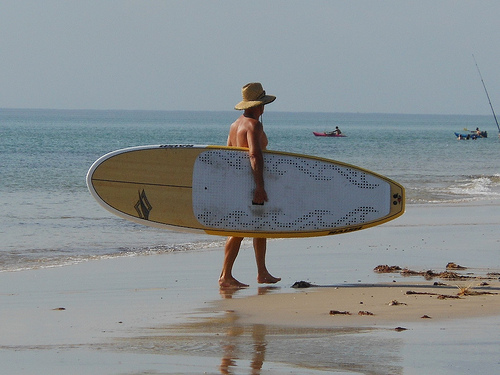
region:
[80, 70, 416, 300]
A surfer on the beach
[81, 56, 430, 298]
A male surfer on the beach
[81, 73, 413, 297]
A person walking on the beach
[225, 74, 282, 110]
A brown sunhat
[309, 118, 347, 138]
A person in the water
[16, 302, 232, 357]
The wet sand on the beach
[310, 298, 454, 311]
The dry sand on the beach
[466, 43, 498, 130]
A tall pole in the sky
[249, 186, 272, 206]
The right hand of the man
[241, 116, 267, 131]
The right shoulder of the man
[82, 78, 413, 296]
a man carrying a surf board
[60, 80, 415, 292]
a man walking on the beach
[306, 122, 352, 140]
a woman jet skiing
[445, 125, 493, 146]
people on a boat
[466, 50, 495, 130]
the end of a fishing rod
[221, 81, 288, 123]
a man wearing a straw hat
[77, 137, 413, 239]
a white, black, and wood designed surf board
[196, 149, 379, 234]
a black and white design on a surf board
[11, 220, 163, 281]
the ocean washing up on the beach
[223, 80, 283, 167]
a man not wearing a shirt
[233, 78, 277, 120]
the head of a man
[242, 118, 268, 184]
the arm of a man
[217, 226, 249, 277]
the leg of a man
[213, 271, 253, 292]
the foot of a man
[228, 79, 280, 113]
a brown straw hat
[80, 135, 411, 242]
a brown and white surfboard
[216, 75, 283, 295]
a man on the beach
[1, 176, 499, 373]
a brown sandy beach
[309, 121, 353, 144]
a red jet ski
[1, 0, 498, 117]
a clear sky overhead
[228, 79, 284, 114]
THE MAN IS WEARING A HAT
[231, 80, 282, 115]
THE MAN'S HAT IS A STRAW HAT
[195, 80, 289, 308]
THE MAN IS WALKING ON THE BEACH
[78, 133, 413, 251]
THE MAN IS CARRYING A SURF BOARD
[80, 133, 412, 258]
THE SURFBOARD IS HUGE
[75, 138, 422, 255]
THE SURFBOARD IS WOODEN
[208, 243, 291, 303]
THE MAN IS BAREFOOT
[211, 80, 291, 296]
THE MAN IS SHIRTLESS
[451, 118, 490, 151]
THE MAN IS IN THE WATER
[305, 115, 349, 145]
THE MAN IS ON A KAYAK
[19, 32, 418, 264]
this is on a beach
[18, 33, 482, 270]
this is along a coast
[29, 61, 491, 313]
this is an outdoor photo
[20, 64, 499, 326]
this is along an ocean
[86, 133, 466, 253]
this is a surfboard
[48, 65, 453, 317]
this man is a surfer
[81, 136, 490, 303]
the board is white and yellow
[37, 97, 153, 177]
this is an ocean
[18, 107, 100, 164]
the ocean is blue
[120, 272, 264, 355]
the ground here is sand